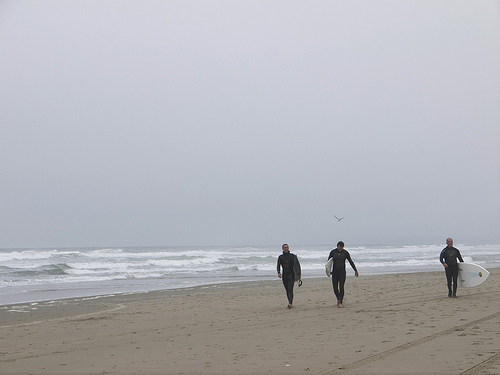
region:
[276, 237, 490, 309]
three surfers are walking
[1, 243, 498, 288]
many ocean waves in background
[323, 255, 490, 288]
two white surfboards being carried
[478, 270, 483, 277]
logo on surfboard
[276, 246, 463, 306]
surfers wearing black wetsuits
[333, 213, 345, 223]
seagull is flying above surfers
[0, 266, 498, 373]
wet sandy beach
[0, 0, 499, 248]
sky is grey and cloudy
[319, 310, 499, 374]
vehicle tracks in the sand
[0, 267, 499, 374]
footprints all over beach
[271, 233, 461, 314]
three people walking a beach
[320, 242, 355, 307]
a black wet suit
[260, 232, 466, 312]
three black wet suits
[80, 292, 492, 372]
brown sand on a beach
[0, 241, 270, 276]
white cresting waves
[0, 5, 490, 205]
a grey sky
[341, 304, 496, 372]
two tire tracks in the sand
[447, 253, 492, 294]
a white surf board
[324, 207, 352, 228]
a bird flying in the sky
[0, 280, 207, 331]
waves coming to shore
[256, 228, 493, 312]
tree surfers walking on the sand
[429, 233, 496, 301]
Surfer holding surfboard under left arm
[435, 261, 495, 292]
Surfboard is white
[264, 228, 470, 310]
Surfers wearing black surf wear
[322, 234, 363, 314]
Surfer carrying surfboard under right arm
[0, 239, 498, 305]
Waves are rolling in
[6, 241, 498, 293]
Waters are agitated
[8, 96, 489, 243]
Sky is cloudy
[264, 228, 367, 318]
Surfers are barefoot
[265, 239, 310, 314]
Surfer holding surfboard under right arm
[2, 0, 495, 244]
the sky is grey in color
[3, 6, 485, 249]
the sky is overcast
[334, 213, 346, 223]
a seagull is flying by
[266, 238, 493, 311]
three surfers are walking along the beach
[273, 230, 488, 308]
the surfers are wearing wetsuits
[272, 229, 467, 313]
the wetsuits are black in color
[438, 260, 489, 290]
the surfboard is white in color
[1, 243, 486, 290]
the ocean is very choppy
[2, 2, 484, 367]
the photo was taken during daytime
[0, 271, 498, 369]
the sand has track marks on it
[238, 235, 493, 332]
a group of men are walking along a beach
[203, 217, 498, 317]
a group of guys are walking with surfboard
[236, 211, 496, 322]
three men are all wearing wetsuits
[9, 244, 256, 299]
the water crashes into the shore of the beach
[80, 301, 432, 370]
wet sand of the beach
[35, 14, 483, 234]
sky is overcast and opaque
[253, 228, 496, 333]
a group of friends walking together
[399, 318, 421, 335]
footprints in the wet sand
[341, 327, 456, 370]
tire tracks in the sand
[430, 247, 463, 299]
a black water suit